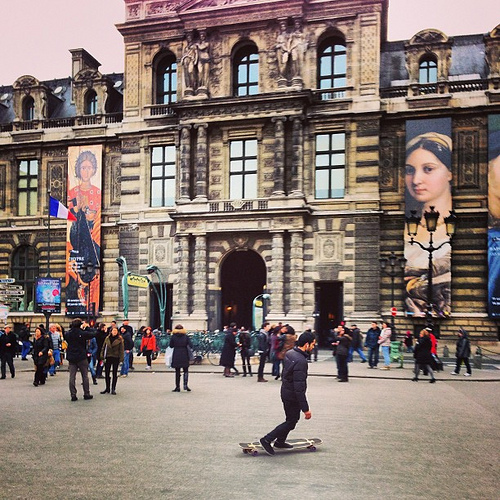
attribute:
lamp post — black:
[411, 212, 455, 323]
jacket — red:
[142, 327, 158, 359]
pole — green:
[156, 263, 172, 333]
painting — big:
[60, 138, 103, 321]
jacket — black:
[171, 329, 197, 398]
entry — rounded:
[226, 238, 274, 331]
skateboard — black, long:
[235, 438, 324, 456]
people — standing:
[69, 312, 351, 390]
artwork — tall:
[406, 121, 458, 303]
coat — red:
[432, 329, 448, 361]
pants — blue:
[384, 347, 396, 368]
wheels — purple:
[240, 443, 262, 458]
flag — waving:
[47, 193, 72, 239]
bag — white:
[163, 340, 180, 364]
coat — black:
[73, 329, 96, 369]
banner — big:
[488, 119, 498, 302]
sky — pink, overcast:
[17, 21, 109, 46]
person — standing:
[164, 318, 200, 404]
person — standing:
[104, 323, 134, 402]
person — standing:
[336, 327, 358, 385]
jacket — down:
[277, 356, 316, 407]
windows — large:
[156, 52, 368, 113]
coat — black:
[217, 332, 240, 376]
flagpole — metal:
[44, 223, 64, 273]